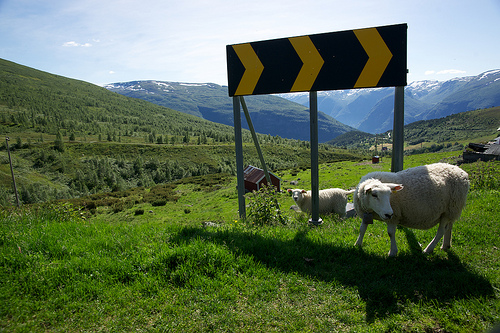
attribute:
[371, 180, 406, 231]
face — white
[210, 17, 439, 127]
sign — yellow, black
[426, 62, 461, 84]
cloud — white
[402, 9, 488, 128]
sky — clear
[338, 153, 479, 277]
sheep — tan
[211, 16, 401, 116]
sign — yellow, black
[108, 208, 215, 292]
grass — thick, green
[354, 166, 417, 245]
face — white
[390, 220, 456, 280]
legs — white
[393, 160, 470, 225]
wool — grey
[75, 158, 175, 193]
trees — green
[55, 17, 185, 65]
clouds — thin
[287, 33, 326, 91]
arrows — yellow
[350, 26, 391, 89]
arrows — yellow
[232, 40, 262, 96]
arrows — yellow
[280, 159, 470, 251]
sheep — standing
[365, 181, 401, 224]
face — white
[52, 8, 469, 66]
skies — blue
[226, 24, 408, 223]
traffic sign — black, yellow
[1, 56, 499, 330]
field — large, open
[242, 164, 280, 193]
building — small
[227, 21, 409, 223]
sign — yellow, black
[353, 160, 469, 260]
sheep — tan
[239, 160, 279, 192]
shack — small, tin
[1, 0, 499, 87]
sky — cloudy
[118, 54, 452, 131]
range —  mountain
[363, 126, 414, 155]
house — small farm 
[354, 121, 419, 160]
house — small farm 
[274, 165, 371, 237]
sheep —  right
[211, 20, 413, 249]
sign — rectangular black and yellow 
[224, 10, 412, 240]
sign —  black and yellow 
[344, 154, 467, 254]
sheep —  standing 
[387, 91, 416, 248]
post — sign 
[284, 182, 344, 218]
sheep — small 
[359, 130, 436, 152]
building — small red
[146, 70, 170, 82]
snow — distant 